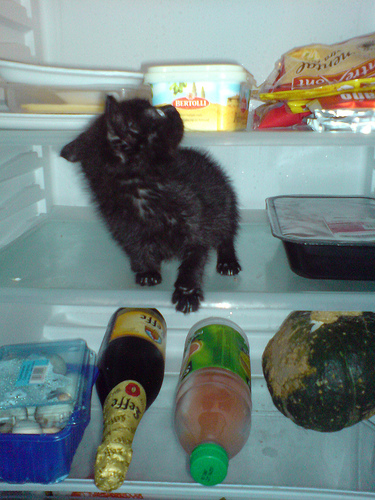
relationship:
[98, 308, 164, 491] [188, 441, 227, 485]
bottle has a lid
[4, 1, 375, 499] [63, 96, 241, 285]
fridge has a kitten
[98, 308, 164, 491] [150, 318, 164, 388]
bottle on its side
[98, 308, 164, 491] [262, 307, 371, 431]
bottle near a pumpkin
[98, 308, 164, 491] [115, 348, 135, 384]
bottle has juice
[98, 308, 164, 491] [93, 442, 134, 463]
bottle has a seal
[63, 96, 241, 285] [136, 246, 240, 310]
cat has legs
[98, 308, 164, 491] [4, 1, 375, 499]
bottle in fridge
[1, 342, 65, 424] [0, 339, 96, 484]
mushrooms are in a container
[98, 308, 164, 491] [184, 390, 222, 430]
bottle made of plastic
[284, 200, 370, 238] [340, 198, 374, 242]
lobster on right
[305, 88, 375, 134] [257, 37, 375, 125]
chips are in a bag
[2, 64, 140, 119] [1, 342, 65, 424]
container has mushrooms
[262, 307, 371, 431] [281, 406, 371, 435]
vegatable has a bottom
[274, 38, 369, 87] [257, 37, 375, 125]
tortillas are in a bag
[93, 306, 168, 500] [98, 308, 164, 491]
champagne in a bottle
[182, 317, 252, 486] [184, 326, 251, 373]
bottle has a green label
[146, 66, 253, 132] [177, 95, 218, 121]
pot has butter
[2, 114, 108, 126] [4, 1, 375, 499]
plate in fridge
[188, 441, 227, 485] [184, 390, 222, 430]
cover made of plastic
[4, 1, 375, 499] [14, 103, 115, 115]
fridge has food